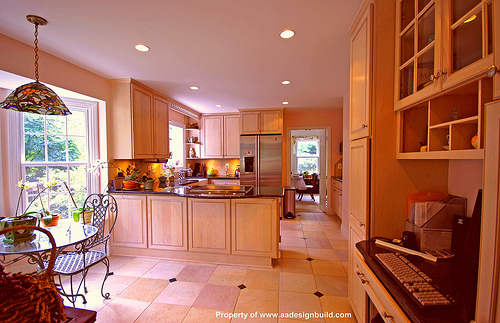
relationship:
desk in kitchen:
[365, 235, 460, 321] [1, 1, 499, 321]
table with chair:
[0, 215, 96, 312] [35, 192, 120, 302]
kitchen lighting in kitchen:
[134, 44, 149, 52] [1, 1, 499, 321]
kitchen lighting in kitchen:
[278, 28, 293, 40] [1, 1, 499, 321]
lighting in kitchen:
[281, 79, 291, 88] [1, 1, 499, 321]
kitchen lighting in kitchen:
[189, 83, 199, 92] [1, 1, 499, 321]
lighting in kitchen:
[280, 99, 290, 106] [1, 1, 499, 321]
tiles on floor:
[56, 242, 355, 319] [54, 191, 361, 319]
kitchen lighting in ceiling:
[282, 28, 293, 38] [0, 0, 370, 117]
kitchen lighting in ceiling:
[135, 44, 146, 52] [0, 0, 370, 117]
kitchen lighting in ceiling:
[189, 83, 199, 92] [0, 0, 370, 117]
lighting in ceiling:
[281, 79, 291, 88] [0, 0, 370, 117]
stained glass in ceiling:
[1, 80, 71, 115] [2, 5, 349, 108]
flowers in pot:
[12, 177, 58, 234] [40, 213, 60, 225]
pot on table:
[40, 213, 60, 225] [1, 214, 94, 260]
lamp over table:
[0, 14, 72, 116] [0, 215, 96, 312]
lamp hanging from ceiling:
[6, 10, 92, 124] [2, 5, 349, 108]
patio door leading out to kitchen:
[19, 110, 108, 211] [22, 49, 384, 317]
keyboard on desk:
[378, 257, 498, 314] [359, 230, 489, 321]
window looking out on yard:
[5, 97, 95, 248] [23, 116, 86, 221]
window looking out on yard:
[167, 117, 189, 174] [23, 116, 86, 221]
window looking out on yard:
[294, 135, 320, 177] [23, 116, 86, 221]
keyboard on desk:
[371, 252, 458, 312] [351, 229, 475, 321]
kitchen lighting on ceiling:
[278, 28, 293, 40] [0, 0, 370, 117]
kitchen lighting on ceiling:
[212, 104, 220, 108] [0, 0, 370, 117]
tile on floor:
[280, 272, 317, 292] [54, 191, 361, 319]